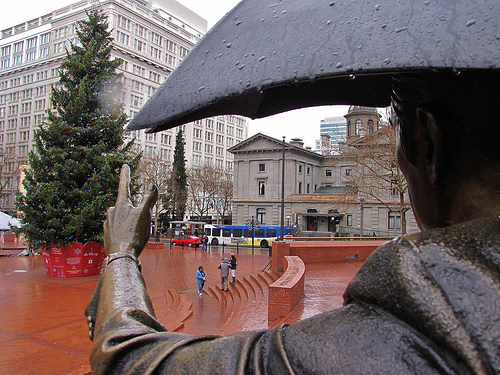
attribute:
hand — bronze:
[96, 162, 159, 246]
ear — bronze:
[414, 103, 446, 192]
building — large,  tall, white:
[10, 16, 260, 236]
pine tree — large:
[10, 2, 146, 249]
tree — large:
[7, 6, 164, 277]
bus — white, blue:
[200, 222, 296, 253]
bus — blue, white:
[195, 221, 300, 251]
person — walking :
[194, 263, 209, 295]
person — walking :
[217, 253, 231, 290]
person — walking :
[225, 251, 240, 283]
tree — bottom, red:
[17, 10, 142, 278]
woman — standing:
[227, 250, 241, 287]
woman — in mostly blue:
[194, 262, 209, 298]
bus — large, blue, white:
[201, 221, 295, 251]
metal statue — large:
[87, 68, 499, 373]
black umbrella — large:
[120, 0, 499, 147]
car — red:
[167, 229, 200, 246]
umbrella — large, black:
[105, 3, 499, 145]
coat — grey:
[223, 256, 239, 281]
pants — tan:
[223, 264, 236, 294]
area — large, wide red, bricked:
[0, 231, 391, 371]